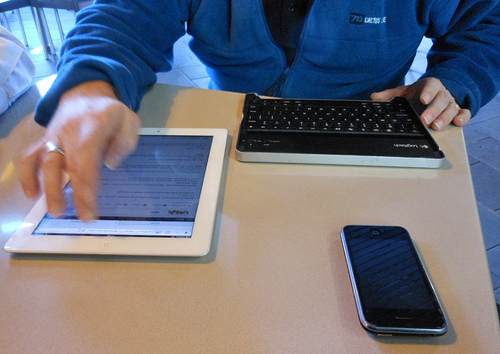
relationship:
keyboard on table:
[228, 87, 445, 171] [0, 65, 499, 352]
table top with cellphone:
[0, 262, 356, 352] [338, 223, 450, 338]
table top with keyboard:
[0, 262, 356, 352] [235, 91, 443, 169]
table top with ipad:
[0, 262, 356, 352] [1, 125, 229, 260]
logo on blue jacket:
[354, 15, 394, 29] [34, 1, 499, 124]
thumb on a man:
[370, 84, 402, 101] [9, 0, 500, 226]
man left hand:
[9, 0, 500, 226] [369, 76, 471, 128]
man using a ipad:
[9, 0, 500, 226] [1, 125, 229, 260]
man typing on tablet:
[82, 0, 474, 102] [66, 118, 243, 274]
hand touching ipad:
[16, 80, 138, 222] [6, 125, 231, 262]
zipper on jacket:
[265, 16, 330, 77] [51, 13, 498, 101]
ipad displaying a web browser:
[4, 107, 229, 258] [31, 134, 217, 237]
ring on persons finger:
[41, 142, 63, 154] [39, 134, 63, 219]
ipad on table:
[1, 125, 229, 260] [0, 65, 499, 352]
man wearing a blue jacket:
[9, 0, 500, 226] [34, 1, 499, 124]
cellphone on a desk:
[340, 219, 460, 343] [0, 83, 500, 350]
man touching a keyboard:
[9, 0, 500, 226] [228, 87, 445, 171]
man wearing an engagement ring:
[9, 0, 500, 226] [36, 128, 75, 161]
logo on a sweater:
[350, 13, 387, 24] [36, 0, 497, 145]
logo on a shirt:
[350, 13, 387, 24] [115, 2, 463, 89]